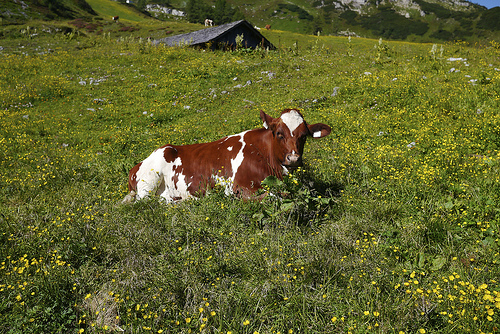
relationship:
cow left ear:
[120, 108, 331, 207] [311, 122, 333, 138]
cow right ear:
[124, 105, 332, 207] [257, 111, 273, 127]